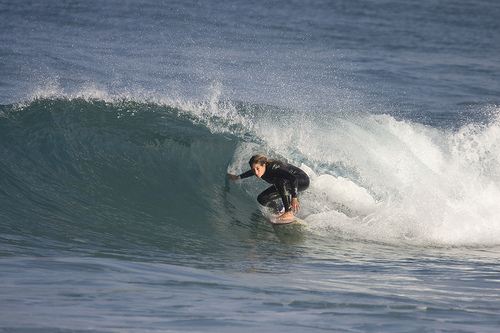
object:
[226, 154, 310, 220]
surfer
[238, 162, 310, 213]
wetsuit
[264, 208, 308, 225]
surfboard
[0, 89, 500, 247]
wave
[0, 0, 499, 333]
ocean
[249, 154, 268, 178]
head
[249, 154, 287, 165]
hair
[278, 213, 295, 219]
foot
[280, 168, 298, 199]
arm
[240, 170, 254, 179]
arm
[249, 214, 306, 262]
reflection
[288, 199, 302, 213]
hand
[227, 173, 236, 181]
hand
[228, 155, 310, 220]
torso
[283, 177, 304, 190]
thigh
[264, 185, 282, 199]
thigh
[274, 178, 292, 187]
knee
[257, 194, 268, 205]
knee